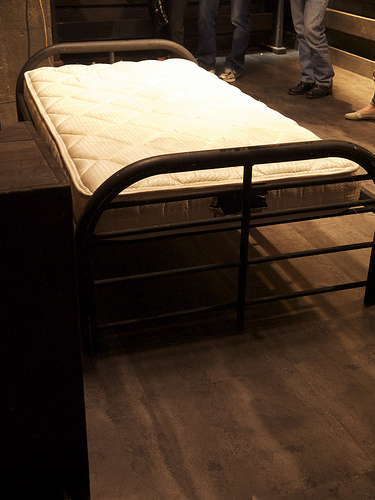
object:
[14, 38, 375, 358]
frame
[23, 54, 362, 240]
mattress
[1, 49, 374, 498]
floor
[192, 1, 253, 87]
person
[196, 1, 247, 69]
jeans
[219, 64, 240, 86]
tennis shoes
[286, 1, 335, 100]
person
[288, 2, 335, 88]
jeans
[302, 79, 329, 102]
black boots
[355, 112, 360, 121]
slip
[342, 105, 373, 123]
shoe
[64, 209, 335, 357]
shadow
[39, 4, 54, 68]
cord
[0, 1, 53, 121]
wall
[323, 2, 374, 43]
slats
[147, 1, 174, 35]
purse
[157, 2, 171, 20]
decorations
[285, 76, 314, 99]
shoes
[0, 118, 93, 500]
chest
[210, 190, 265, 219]
tag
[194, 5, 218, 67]
leg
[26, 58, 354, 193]
top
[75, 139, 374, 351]
front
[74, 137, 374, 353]
railing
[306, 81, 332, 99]
shoe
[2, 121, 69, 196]
top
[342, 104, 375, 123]
foot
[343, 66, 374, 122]
woman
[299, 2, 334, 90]
legs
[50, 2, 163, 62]
shelf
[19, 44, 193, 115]
part